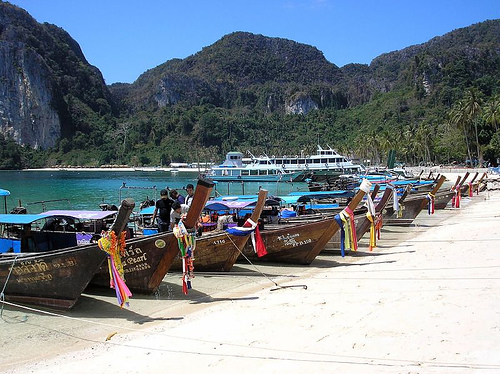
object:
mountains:
[143, 14, 382, 151]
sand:
[2, 160, 499, 371]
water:
[36, 156, 293, 208]